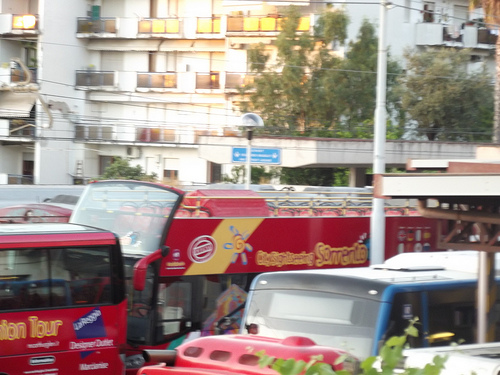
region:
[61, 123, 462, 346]
the is a bus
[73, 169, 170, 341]
front window on bus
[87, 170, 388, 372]
the bus is red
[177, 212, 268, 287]
yellow stripe on bus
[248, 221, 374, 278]
yellow writing on bus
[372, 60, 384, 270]
the light post is white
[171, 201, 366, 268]
the bus is red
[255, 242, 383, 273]
the words are yellow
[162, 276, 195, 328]
side window on the bus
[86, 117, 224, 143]
gates on the balconies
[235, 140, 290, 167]
the sign is blue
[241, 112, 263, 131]
the lamp is silver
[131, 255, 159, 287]
the side mirror is red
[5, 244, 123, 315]
windows on the bus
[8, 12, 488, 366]
traffic jam in front of white building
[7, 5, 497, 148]
building with terraces across floors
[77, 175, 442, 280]
top level of bus filled with empty seats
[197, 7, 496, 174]
trees growing on top of elevated platform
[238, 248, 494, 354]
front and side windows below white roof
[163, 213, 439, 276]
red and yellow panel on side of bus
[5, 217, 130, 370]
tinted windows on back of red bus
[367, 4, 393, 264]
tall white pole narrowing toward top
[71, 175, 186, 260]
slanted windshield on front of top level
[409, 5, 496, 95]
building terraces above trees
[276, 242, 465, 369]
a bus on the road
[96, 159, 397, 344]
a bus on the road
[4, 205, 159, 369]
a bus on the road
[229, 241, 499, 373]
a bus on the street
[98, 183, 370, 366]
a bus on the street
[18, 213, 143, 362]
a bus on teh street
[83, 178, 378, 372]
a red bus on the road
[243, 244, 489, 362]
a blue bus on the road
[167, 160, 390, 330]
a passenger bus outside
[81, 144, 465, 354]
the bus is red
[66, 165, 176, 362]
front window on red bus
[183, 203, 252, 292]
yellow trim on bus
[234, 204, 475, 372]
a white and blue bus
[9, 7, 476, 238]
residential building in background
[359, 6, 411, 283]
a white pole on side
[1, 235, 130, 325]
side window of the bus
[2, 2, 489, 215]
Apartments can be seen in the background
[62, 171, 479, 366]
Double Decker bus has no roof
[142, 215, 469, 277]
Bus has writing on the side of it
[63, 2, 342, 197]
Patios have a protective wall on them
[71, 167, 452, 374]
tall red and yellow bus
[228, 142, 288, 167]
blue and white street sign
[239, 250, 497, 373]
blue and white bus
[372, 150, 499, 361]
covered area of a bus stop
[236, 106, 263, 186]
light post near a bus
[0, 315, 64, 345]
yellow words on a tour bus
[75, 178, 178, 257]
second level window on a bus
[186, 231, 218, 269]
round red logo on a red bus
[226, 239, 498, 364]
The blue bus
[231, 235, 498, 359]
A blue bus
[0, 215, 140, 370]
The partially visible red bus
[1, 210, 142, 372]
A partially visible red bus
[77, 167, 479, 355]
The red bus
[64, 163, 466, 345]
A red passenger bus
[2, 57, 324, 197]
The white building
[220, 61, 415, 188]
The large green tree in front the building